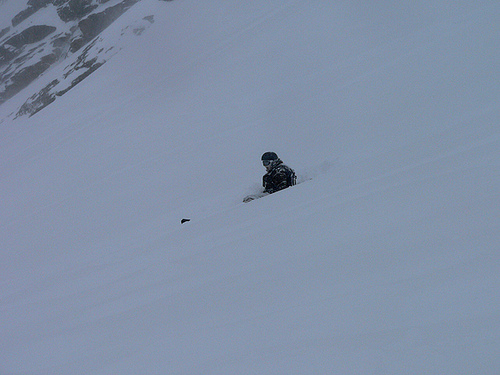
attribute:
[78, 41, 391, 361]
slope — white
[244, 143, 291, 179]
hat — black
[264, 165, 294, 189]
jacket — black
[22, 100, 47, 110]
rock — grey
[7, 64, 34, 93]
rock — grey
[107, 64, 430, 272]
mountain — white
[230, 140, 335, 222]
person — sitting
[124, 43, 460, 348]
snow — white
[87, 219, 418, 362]
snow — white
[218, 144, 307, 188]
jacket — black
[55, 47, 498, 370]
slope — covered, snow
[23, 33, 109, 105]
rock — grey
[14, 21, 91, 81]
rock — grey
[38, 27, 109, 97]
rock — grey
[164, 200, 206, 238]
foot — black